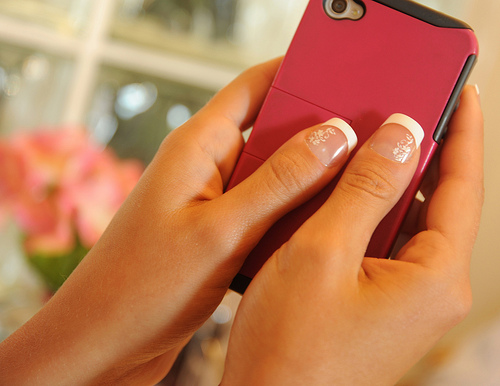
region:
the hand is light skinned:
[327, 285, 442, 339]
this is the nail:
[372, 117, 422, 153]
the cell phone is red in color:
[354, 26, 422, 94]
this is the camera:
[317, 0, 359, 25]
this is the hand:
[12, 315, 107, 383]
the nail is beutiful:
[372, 115, 419, 156]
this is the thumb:
[330, 143, 410, 241]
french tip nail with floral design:
[373, 108, 423, 169]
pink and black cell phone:
[221, 1, 477, 296]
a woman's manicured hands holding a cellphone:
[0, 50, 481, 380]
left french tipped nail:
[304, 113, 358, 168]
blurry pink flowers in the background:
[1, 121, 147, 294]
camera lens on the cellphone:
[318, 0, 371, 30]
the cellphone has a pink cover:
[218, 0, 478, 315]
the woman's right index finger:
[411, 79, 483, 259]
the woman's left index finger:
[192, 50, 292, 129]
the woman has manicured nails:
[303, 79, 481, 168]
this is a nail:
[308, 113, 355, 165]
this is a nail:
[367, 112, 423, 161]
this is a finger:
[436, 85, 498, 277]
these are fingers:
[219, 123, 426, 265]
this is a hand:
[233, 100, 498, 384]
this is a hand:
[0, 44, 347, 384]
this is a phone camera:
[317, 0, 367, 25]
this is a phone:
[202, 2, 466, 284]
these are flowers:
[1, 127, 145, 284]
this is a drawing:
[388, 130, 421, 160]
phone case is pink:
[248, 0, 453, 314]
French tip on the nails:
[272, 82, 443, 208]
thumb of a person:
[215, 107, 365, 230]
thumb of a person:
[308, 110, 424, 266]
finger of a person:
[185, 33, 312, 121]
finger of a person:
[433, 75, 490, 222]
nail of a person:
[371, 110, 431, 167]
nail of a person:
[292, 118, 356, 175]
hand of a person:
[38, 51, 343, 371]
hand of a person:
[265, 64, 492, 369]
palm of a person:
[98, 250, 255, 347]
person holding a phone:
[194, 2, 466, 309]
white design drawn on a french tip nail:
[371, 109, 423, 174]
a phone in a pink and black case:
[229, 0, 476, 318]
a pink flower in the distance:
[11, 117, 160, 267]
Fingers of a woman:
[213, 111, 429, 287]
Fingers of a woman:
[257, 109, 427, 251]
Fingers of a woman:
[241, 106, 431, 253]